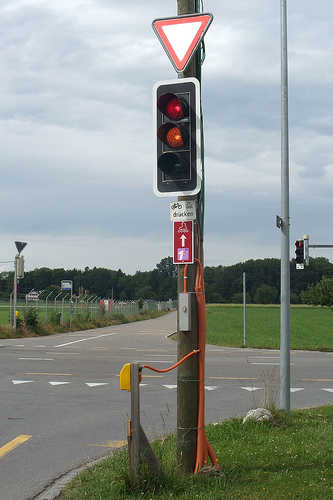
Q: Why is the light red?
A: To stop traffic.